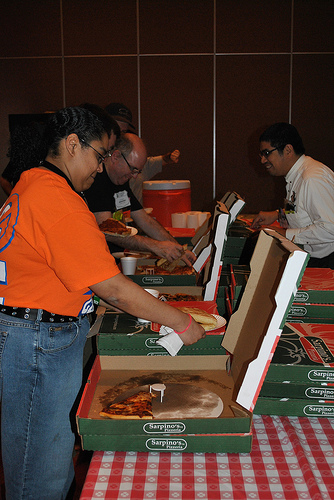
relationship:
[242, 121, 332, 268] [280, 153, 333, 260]
man wearing shirt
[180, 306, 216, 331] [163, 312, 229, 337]
pizza on plate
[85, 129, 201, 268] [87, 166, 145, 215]
man wearing tshirt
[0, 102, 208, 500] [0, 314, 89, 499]
woman wearing jeans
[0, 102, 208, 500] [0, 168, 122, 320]
woman wearing tshirt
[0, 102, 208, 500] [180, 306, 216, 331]
woman getting pizza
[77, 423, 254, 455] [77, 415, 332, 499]
box on tablecloth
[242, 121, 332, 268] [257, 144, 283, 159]
man has glasses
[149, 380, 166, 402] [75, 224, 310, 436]
pizza divider in box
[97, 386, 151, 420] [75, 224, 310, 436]
pizza slice in box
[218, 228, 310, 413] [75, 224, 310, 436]
cover on box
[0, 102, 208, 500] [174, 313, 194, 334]
woman wearing bracelet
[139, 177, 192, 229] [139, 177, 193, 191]
cooler has lid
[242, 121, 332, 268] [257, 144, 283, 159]
man wearing glasses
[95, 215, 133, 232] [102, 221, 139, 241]
pizza slice on plate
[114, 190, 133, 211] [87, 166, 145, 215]
name tag on tshirt